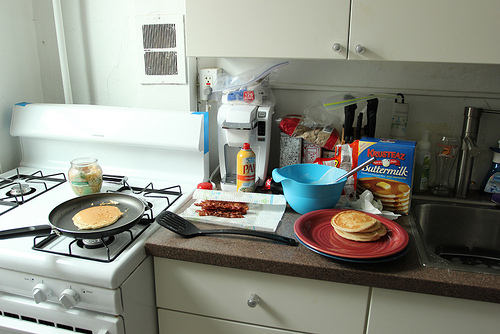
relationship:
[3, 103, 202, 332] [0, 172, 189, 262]
stove have black burners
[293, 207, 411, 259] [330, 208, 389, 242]
plate have pancakes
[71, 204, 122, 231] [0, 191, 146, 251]
pancakes are in frying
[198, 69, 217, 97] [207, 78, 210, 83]
electric outlet have three prong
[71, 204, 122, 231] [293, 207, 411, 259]
pancakes in red dish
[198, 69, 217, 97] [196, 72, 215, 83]
electric outlet have one available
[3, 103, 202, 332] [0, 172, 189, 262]
stove have five burners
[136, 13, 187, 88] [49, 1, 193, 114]
exhaust vent in wall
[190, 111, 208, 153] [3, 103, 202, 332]
masking tape on stove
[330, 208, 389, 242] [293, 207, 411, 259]
pancakes are in plate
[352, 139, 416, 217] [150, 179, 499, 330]
pancake mix box on counter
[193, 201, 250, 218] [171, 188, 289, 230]
bacon on paper towel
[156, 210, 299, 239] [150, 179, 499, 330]
spatula on counter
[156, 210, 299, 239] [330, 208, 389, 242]
spatula next pancakes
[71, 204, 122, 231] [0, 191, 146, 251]
pancake in frying pan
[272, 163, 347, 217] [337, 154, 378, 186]
bowl have a whisk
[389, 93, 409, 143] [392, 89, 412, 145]
paper towel on holder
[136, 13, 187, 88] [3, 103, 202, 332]
vents are above stove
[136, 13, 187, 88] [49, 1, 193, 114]
vents are on wall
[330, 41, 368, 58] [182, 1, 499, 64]
knobs are on cabinet doors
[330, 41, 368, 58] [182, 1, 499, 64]
knobs are in cabinet doors